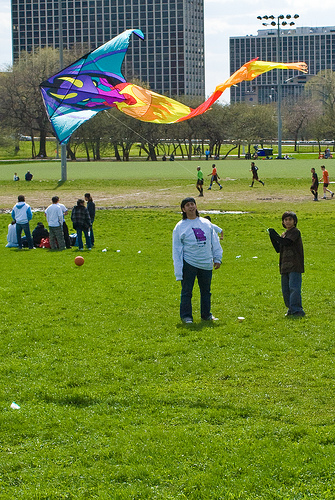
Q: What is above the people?
A: Long multi colored kite.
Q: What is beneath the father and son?
A: Green grass in park.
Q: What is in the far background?
A: Tall building with many windows.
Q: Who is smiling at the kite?
A: Boy in light grey sweatshirt.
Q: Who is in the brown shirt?
A: Boy flying a kite.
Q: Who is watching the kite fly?
A: Two people standing in park.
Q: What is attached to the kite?
A: String.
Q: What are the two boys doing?
A: Flying a kite.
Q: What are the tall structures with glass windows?
A: Buildings.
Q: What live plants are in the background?
A: Trees.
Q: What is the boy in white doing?
A: Watching.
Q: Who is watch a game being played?
A: A group.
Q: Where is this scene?
A: A park.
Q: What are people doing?
A: Flying kite.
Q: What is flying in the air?
A: Kite.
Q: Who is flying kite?
A: A child.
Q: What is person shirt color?
A: White.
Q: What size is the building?
A: Tall.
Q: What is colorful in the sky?
A: Kite.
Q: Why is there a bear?
A: There isn't one.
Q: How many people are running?
A: One.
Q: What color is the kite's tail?
A: Orange and yellow.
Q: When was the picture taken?
A: Daytime.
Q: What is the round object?
A: A ball.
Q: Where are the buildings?
A: In the back.